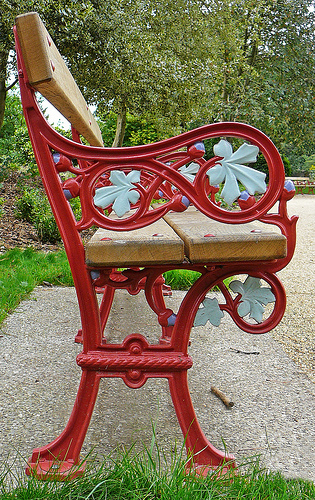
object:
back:
[14, 12, 104, 147]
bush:
[13, 171, 81, 244]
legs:
[25, 264, 285, 488]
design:
[206, 139, 266, 205]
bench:
[13, 11, 299, 487]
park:
[0, 0, 315, 498]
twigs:
[211, 384, 234, 407]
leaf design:
[193, 296, 226, 327]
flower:
[170, 194, 189, 212]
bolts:
[85, 204, 287, 266]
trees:
[0, 1, 315, 185]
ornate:
[31, 110, 284, 231]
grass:
[0, 438, 315, 499]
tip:
[167, 314, 176, 327]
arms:
[20, 87, 284, 230]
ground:
[0, 195, 315, 500]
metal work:
[13, 25, 299, 487]